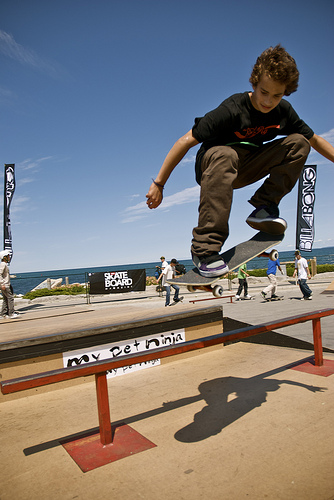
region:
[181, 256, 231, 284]
boy with purple and white shoes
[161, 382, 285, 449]
reflection from the boy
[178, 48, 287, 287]
boy on a skateboard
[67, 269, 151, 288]
sign with white letters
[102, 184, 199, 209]
clouds in the sky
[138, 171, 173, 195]
wearing a wrist band on right hand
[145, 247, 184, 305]
boy in white shirt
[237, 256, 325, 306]
three people in the background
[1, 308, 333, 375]
ramp that boy goes on to skateboard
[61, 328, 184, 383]
sign on the board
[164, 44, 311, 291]
Boy riding a skateboard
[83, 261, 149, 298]
Black banner with white lettering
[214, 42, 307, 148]
Boy wearing black tshirt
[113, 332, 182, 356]
White sign with black lettering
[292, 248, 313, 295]
Boy wearing white tshirt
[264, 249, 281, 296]
Boy wearing blue tshirt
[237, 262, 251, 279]
Boy wearing green tshirt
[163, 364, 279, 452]
Shadow on ground of skateboarder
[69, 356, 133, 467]
Red and black skateboarding rail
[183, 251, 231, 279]
Purple and gray sneakers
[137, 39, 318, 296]
a boy on a skateboard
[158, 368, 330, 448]
the shadow of a boy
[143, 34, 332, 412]
a boy doing a skateboard trick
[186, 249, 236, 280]
a purple and white shoe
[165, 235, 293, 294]
a wooden skate board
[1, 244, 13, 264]
a kid wearing a white helmet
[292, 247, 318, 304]
a man skateboarding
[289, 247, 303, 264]
a man wearing a baseball cap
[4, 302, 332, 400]
a skateboarding rail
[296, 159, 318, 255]
a black and white banner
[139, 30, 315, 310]
the boy is in the air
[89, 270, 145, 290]
the banner is black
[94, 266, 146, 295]
the banner says "skate board"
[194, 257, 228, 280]
the shoes are purple and gray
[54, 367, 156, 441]
the railing is orange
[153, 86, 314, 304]
the boy is skateboarding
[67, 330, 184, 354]
the sign reads "my pet ninja"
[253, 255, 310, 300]
the kids are skateboarding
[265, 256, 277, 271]
the shirt is blue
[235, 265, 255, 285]
the shirt is green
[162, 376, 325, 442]
shadow of skateboarder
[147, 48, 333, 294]
boy on skateboard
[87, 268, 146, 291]
black skateboard park sign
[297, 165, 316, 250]
black billabong flag on a pole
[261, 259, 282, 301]
skateboarder in a blue shirt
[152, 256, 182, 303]
skateboarder in a white shirt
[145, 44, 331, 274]
boy on skateboard above railing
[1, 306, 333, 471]
red skateboard railing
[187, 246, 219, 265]
purple shoes on boy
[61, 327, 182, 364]
white sign that say "my pet ninja"